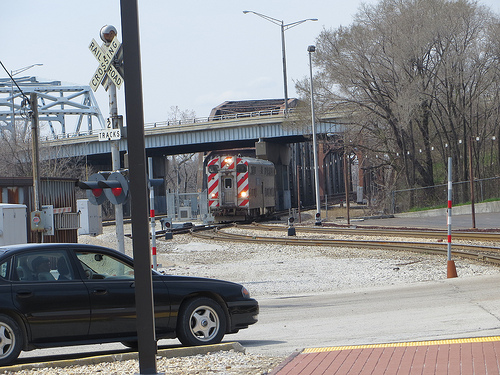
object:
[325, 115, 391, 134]
floor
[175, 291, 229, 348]
tire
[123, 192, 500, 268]
train tracks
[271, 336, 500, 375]
brick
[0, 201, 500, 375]
ground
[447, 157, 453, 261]
pole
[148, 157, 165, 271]
pole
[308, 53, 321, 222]
pole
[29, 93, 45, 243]
pole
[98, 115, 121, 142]
sign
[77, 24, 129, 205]
equipment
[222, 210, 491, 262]
tracks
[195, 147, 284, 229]
train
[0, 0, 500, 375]
city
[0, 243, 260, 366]
car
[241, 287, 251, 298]
headlight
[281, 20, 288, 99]
post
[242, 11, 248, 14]
light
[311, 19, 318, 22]
light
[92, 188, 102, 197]
light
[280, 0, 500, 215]
trees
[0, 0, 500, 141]
blue sky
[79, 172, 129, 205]
sign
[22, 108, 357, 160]
bridge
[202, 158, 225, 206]
stripes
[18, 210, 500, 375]
crossing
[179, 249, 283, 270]
rocks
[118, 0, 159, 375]
pole